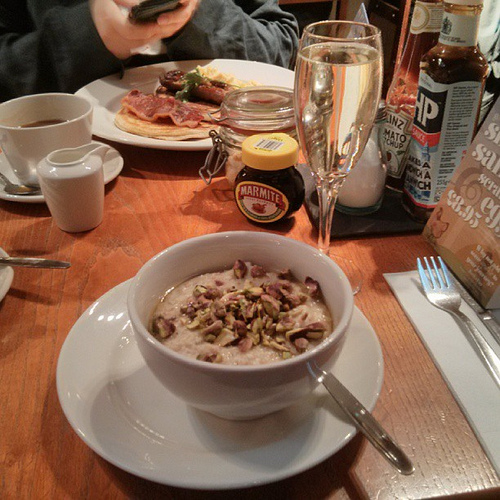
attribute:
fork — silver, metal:
[416, 255, 499, 393]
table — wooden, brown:
[1, 99, 498, 500]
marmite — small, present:
[232, 131, 305, 227]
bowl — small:
[127, 230, 355, 424]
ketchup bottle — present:
[378, 0, 442, 194]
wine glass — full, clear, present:
[294, 19, 383, 296]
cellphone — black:
[130, 0, 178, 23]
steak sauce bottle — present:
[400, 0, 489, 226]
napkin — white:
[381, 269, 499, 481]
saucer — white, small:
[0, 139, 125, 201]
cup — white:
[0, 91, 92, 188]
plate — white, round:
[56, 277, 383, 491]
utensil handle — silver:
[3, 258, 73, 268]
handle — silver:
[453, 309, 500, 386]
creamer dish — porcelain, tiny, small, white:
[36, 142, 109, 232]